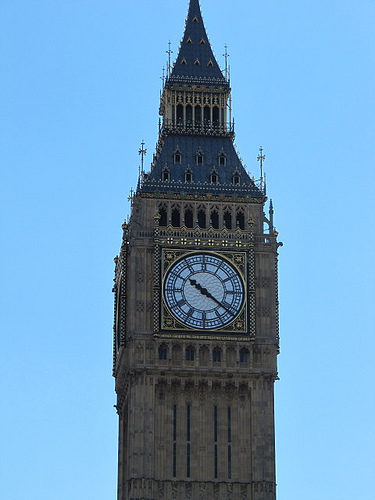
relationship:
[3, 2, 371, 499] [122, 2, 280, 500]
scene shows tower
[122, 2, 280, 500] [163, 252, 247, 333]
tower has clock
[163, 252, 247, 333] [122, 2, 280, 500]
clock on front of tower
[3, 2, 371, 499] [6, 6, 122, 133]
scene shows sky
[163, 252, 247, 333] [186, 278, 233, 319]
clock has hands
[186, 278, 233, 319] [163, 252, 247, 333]
hands are on clock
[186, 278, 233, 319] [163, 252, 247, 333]
hands are a part of clock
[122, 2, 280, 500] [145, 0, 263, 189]
tower has steeple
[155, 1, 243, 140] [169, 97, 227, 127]
steeple has decorative arches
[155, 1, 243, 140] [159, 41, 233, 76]
steeple has crosses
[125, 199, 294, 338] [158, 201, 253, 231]
tower-top shows windows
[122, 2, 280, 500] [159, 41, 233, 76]
tower has crosses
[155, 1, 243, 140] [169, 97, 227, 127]
steeple has arched windows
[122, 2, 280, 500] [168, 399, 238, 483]
tower front shows vertical openings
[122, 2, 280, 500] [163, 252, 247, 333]
tower has face of clock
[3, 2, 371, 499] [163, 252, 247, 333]
scene shows mark on clock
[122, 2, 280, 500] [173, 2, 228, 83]
tower has top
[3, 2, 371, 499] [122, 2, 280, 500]
scene features clock tower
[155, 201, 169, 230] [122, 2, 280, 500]
window on tower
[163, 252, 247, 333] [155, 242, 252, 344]
clock has frame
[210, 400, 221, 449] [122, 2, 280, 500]
slit part of tower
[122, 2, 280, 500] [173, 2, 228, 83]
tower has roof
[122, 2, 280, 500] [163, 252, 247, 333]
tower has notch on clock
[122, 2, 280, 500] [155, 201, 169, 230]
tower has window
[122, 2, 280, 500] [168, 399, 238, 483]
tower shows vertical openings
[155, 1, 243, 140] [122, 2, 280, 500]
steeple at top of tower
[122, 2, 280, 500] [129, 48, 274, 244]
tower shows ornamentation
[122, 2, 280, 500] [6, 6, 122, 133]
tower beneath sky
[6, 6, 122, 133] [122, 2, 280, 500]
sky topping tower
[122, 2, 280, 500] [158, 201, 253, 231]
tower has windows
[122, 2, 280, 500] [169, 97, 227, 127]
tower windows have decorative arches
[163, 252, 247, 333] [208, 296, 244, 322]
clock has minute hand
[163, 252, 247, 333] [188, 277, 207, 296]
clock has hour hand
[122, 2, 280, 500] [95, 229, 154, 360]
tower shows corners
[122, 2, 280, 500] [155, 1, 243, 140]
tower has roof which steeple